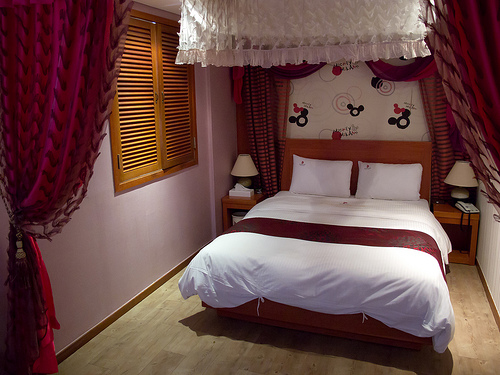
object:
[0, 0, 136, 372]
curtain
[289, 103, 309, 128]
decal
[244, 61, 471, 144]
wall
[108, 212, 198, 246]
wall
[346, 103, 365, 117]
decal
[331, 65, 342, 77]
decal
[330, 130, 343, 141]
decal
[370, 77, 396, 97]
decal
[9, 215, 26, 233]
tieback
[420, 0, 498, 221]
curtain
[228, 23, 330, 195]
curtain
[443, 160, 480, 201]
lamp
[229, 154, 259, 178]
lampshade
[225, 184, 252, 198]
tissues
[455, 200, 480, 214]
landline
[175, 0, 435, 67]
canopy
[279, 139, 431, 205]
headboard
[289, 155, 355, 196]
pillow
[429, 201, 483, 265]
nightstand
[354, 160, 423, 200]
pillow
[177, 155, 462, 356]
comforter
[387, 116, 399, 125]
ears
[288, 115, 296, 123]
ears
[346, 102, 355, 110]
ears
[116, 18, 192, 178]
blinds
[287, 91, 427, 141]
design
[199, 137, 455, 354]
bed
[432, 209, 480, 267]
endstone